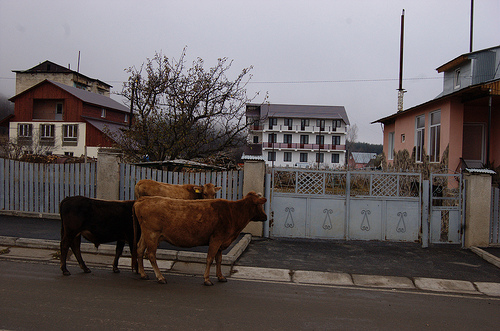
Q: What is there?
A: Animals.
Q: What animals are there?
A: Cows.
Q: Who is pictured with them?
A: No one.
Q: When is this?
A: Early evening.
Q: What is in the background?
A: Houses.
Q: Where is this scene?
A: Neighborhood.